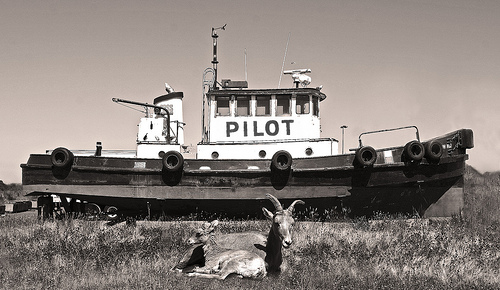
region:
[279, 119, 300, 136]
letter t on the side of a ship.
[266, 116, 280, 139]
letter o on the side of a ship.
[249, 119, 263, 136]
letter l on the side of a ship.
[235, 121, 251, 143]
letter i on the side of a ship.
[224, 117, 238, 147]
letter p on the side of a ship.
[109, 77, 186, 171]
large smoke stack on a ship.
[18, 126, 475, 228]
Large hull of a ship.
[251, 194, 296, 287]
small tree in a field.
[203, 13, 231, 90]
Pole sticking out of a ship.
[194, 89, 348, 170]
small structure on a ship.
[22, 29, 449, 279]
The photo is in black and white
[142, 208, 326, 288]
The animal is laying down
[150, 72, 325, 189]
The boat says pilot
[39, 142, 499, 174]
The boat has tires on it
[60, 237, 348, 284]
There is grass around the animal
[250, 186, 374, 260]
The animal has horns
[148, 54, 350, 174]
The top of the boat is white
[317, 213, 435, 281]
The grass is tall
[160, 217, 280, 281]
There is a smaller animal in front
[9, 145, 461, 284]
The boat is on land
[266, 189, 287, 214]
a horn of a goat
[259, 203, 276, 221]
an ear of a goat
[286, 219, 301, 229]
an eye of goat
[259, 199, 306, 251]
a head of a goat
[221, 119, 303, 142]
the word "PILOT" on the side of a boat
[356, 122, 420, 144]
a hand rail on a boat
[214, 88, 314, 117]
windows on a boat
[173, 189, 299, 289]
a herd of goats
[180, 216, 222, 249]
a head of a goat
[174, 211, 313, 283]
goats resting on the ground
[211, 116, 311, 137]
the word "pilot" in black lettering on white background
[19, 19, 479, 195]
boat on dry land with word "pilot" on it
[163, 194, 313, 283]
ram lying in grass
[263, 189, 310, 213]
two horns of ram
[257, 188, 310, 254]
two horned ram's head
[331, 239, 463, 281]
patch of grass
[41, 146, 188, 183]
black mini tires on side of boat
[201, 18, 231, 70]
weather vane on top of boat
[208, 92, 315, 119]
windows on white boat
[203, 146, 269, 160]
round dark holes on side of boat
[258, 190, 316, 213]
The Horns of a Goat.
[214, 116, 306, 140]
The letters spelling out the word "Pilot"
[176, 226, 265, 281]
A sitting dear.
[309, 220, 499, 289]
Grassy plains of varying heights.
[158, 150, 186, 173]
A tire on the side of a boat.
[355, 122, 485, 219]
The front side of the boat.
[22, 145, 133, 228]
The rear side of a boat.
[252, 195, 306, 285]
A goat sitting on the grass.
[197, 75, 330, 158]
The command center of a boat.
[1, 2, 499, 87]
The sky above the boat and plains.